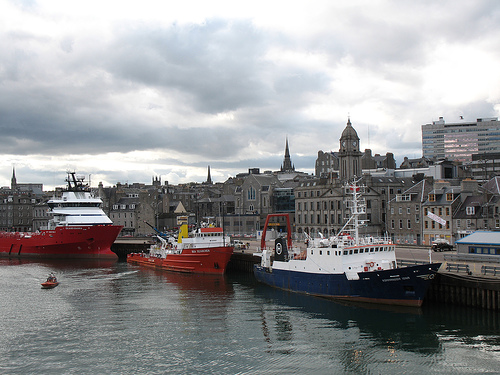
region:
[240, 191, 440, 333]
Blue and white boat on the water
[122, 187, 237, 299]
Red and white boat on the water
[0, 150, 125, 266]
Red and white boat on the water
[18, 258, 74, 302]
Small boat in the water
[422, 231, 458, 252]
Vehicle parked on the pavement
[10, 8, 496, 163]
White clouds in the sky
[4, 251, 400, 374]
Ripples in the water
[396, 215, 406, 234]
Small window on a building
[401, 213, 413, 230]
Small window on a building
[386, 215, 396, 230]
Small window on a building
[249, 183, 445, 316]
Boat in the water.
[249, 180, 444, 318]
Blue bottom on the boat.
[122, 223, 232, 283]
Red bottom on the boat.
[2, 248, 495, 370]
Water in the forefront.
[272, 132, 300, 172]
Steeple in the background.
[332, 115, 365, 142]
domed top on the building.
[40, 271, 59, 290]
Person on the boat.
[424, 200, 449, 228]
Sign on the building.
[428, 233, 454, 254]
Vehicle on the road.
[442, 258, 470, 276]
Railing on the road.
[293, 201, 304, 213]
Small window on a building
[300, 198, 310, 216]
Small window on a building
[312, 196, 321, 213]
Small window on a building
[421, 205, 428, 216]
Small window on a building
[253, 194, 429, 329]
Blue and white boat in the water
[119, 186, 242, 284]
REd and white boat in the water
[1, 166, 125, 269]
REd and white boat in the water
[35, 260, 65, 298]
Small boat in the water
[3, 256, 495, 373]
Small ripples in the water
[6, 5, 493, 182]
Clouds in the sky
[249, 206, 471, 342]
boat docked on port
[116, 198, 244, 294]
boat docked on port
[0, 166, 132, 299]
boat docked on port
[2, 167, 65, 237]
tall city building in back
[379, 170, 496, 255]
tall city building in back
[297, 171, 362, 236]
tall city building in back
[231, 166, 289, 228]
tall city building in back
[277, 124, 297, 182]
tall city building in back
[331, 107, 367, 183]
tall city building in back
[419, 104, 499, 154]
tall city building in back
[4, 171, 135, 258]
Big red and white boat in the back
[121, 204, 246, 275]
Small orange and white boat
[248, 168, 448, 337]
Large blue and white boat in the front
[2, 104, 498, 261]
Alot of buildings behind the boats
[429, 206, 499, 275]
Small blue and white building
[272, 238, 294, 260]
White logo on blue and white boat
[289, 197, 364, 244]
Two rows of tall windows on building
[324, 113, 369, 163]
Pointed temple on building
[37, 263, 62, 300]
Small red and yellow jet ski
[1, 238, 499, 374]
Dark blue water